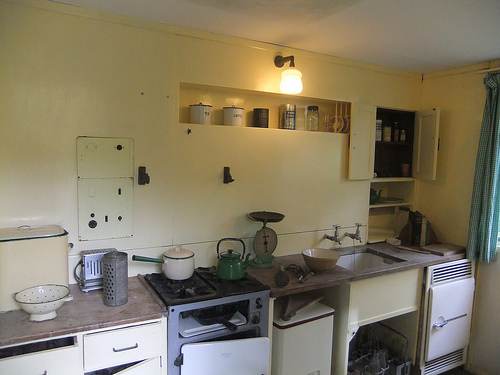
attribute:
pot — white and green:
[132, 245, 194, 280]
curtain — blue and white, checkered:
[459, 74, 498, 270]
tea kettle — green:
[212, 237, 252, 281]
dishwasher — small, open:
[350, 306, 416, 373]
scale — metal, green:
[247, 211, 284, 271]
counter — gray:
[242, 253, 350, 296]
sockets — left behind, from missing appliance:
[74, 135, 136, 243]